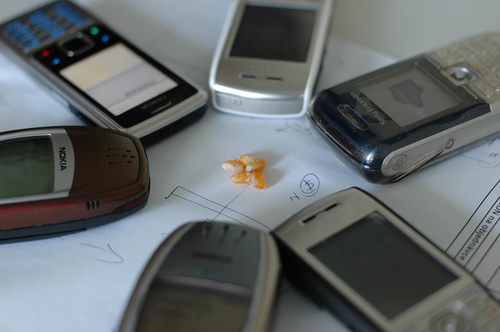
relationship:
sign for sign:
[299, 171, 323, 198] [299, 171, 323, 198]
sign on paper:
[299, 171, 323, 198] [163, 122, 307, 156]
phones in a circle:
[6, 7, 495, 325] [130, 91, 388, 237]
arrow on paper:
[68, 237, 128, 268] [163, 122, 307, 156]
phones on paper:
[6, 7, 495, 325] [163, 122, 307, 156]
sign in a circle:
[299, 171, 323, 198] [130, 91, 388, 237]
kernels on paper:
[221, 151, 268, 189] [163, 122, 307, 156]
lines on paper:
[170, 182, 256, 224] [163, 122, 307, 156]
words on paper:
[459, 207, 497, 261] [163, 122, 307, 156]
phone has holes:
[114, 219, 284, 331] [204, 220, 247, 246]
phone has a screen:
[114, 219, 284, 331] [136, 281, 253, 330]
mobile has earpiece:
[208, 4, 335, 119] [237, 69, 293, 88]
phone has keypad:
[309, 33, 496, 180] [430, 30, 499, 99]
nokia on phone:
[58, 144, 68, 172] [1, 125, 149, 240]